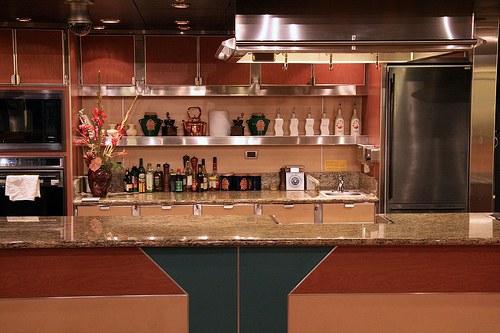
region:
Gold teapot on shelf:
[175, 105, 205, 137]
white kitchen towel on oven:
[0, 170, 45, 200]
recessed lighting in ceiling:
[160, 0, 200, 35]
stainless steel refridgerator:
[375, 60, 465, 210]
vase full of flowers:
[80, 90, 120, 195]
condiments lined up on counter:
[120, 155, 265, 190]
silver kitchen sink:
[320, 170, 365, 200]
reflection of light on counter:
[95, 230, 375, 245]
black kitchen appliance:
[0, 90, 65, 155]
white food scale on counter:
[280, 162, 305, 192]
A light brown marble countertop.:
[3, 182, 498, 244]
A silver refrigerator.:
[386, 67, 470, 212]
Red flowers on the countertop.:
[74, 83, 125, 198]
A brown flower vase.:
[87, 165, 112, 197]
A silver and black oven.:
[2, 157, 63, 214]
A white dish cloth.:
[4, 175, 42, 200]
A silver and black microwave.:
[4, 88, 66, 152]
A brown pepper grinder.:
[164, 159, 170, 192]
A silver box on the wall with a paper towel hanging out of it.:
[354, 142, 369, 172]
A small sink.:
[326, 169, 365, 196]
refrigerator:
[380, 68, 470, 210]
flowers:
[81, 108, 118, 169]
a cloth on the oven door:
[4, 173, 44, 204]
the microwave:
[4, 91, 63, 146]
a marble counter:
[110, 210, 269, 239]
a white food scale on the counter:
[285, 165, 305, 187]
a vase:
[86, 165, 111, 195]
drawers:
[325, 205, 375, 220]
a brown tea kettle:
[180, 106, 208, 133]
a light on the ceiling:
[100, 15, 123, 35]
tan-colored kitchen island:
[0, 210, 498, 250]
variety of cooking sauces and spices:
[122, 153, 220, 192]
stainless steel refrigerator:
[363, 60, 473, 215]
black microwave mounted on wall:
[1, 89, 66, 151]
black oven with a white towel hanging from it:
[0, 155, 67, 217]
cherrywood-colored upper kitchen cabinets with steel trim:
[1, 27, 367, 86]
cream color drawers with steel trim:
[76, 202, 376, 224]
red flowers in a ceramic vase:
[71, 67, 141, 197]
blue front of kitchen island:
[139, 245, 335, 331]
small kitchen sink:
[318, 172, 366, 198]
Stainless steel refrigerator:
[380, 61, 472, 219]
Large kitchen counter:
[0, 211, 497, 248]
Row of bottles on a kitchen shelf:
[273, 101, 368, 145]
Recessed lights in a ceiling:
[0, 0, 199, 37]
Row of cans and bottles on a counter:
[121, 152, 263, 199]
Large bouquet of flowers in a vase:
[72, 69, 142, 201]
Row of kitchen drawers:
[73, 200, 378, 223]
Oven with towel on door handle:
[0, 155, 67, 215]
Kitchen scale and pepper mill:
[278, 162, 305, 191]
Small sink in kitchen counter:
[319, 171, 374, 203]